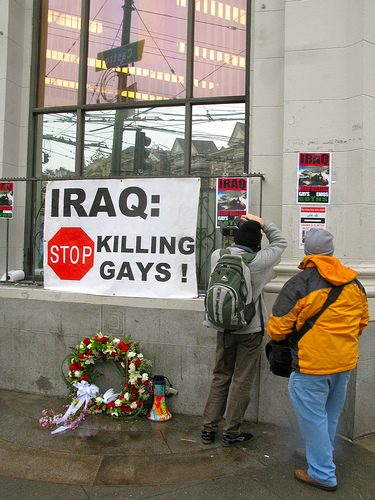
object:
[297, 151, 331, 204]
paper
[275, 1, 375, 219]
wall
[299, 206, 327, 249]
paper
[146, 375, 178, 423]
microphone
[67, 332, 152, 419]
wreath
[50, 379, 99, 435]
ribbon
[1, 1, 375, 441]
building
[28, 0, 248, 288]
window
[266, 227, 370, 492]
person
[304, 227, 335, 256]
hat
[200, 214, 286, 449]
person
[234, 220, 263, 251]
hat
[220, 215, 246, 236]
camera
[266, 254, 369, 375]
jacket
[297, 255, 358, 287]
hood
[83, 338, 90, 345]
flower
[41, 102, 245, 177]
relection of house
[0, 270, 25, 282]
paper towel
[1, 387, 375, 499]
floor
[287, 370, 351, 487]
pants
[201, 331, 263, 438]
pants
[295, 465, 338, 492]
shoes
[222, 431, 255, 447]
shoes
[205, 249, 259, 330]
bag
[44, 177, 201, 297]
board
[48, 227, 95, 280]
symbol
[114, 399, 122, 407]
flower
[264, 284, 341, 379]
bag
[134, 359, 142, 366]
flower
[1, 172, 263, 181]
railing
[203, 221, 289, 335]
shirt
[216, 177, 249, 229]
paper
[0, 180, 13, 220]
paper